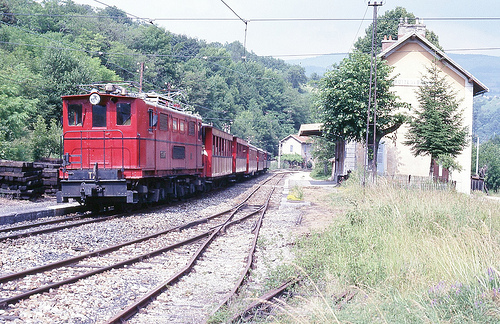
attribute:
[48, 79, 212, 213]
caboose — red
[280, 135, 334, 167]
building — white, small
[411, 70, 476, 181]
tree — evergreen, stately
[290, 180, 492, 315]
grass — growing, tall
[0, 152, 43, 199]
pallet — wood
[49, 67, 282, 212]
train — red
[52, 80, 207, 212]
car — red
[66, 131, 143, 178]
gate — metal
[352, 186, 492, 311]
grass — overgrown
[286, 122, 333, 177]
train station — old, abandoned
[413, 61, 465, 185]
tree — green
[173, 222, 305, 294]
tracks — train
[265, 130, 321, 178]
home — small, yellow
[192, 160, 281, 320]
railroad — long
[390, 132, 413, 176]
side — building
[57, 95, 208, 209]
line — end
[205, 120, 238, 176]
cars — train, red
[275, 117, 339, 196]
station — train